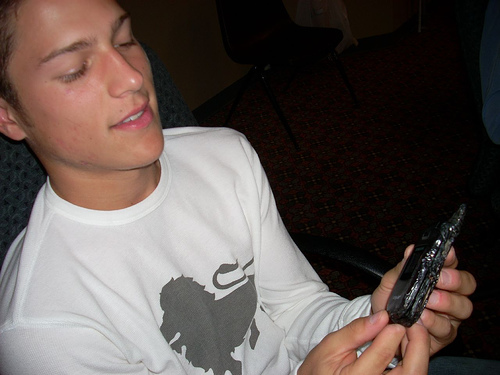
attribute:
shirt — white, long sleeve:
[0, 125, 398, 373]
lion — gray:
[159, 257, 266, 374]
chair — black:
[214, 0, 362, 148]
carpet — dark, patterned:
[199, 25, 498, 360]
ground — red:
[199, 0, 499, 362]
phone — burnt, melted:
[387, 207, 464, 325]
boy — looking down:
[1, 2, 266, 373]